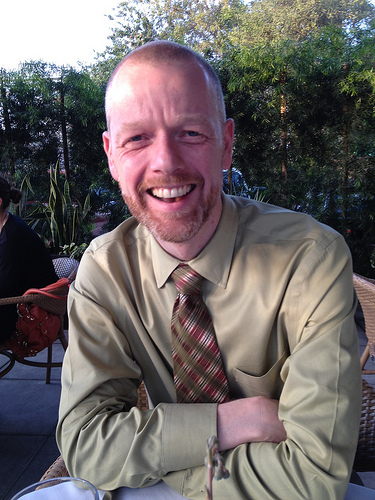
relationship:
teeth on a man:
[150, 183, 195, 198] [52, 40, 361, 498]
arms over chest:
[66, 365, 339, 497] [107, 237, 282, 404]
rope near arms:
[204, 435, 220, 498] [54, 257, 363, 497]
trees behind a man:
[238, 2, 371, 195] [52, 40, 361, 498]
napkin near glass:
[24, 476, 107, 499] [8, 474, 100, 498]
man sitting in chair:
[55, 40, 363, 500] [1, 249, 81, 374]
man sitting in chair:
[52, 40, 361, 498] [346, 267, 373, 370]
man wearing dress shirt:
[52, 40, 361, 498] [55, 189, 362, 499]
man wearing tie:
[52, 40, 361, 498] [169, 266, 229, 403]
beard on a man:
[122, 192, 219, 242] [52, 40, 361, 498]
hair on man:
[104, 40, 226, 132] [87, 50, 260, 313]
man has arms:
[55, 40, 363, 500] [49, 340, 372, 494]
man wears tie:
[55, 40, 363, 500] [165, 256, 220, 407]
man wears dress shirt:
[55, 40, 363, 500] [55, 189, 362, 499]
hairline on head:
[113, 38, 213, 82] [92, 34, 238, 150]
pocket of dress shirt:
[233, 356, 286, 395] [55, 189, 362, 499]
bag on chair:
[23, 275, 73, 301] [2, 253, 83, 388]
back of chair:
[20, 271, 88, 351] [2, 253, 83, 388]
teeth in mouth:
[152, 185, 191, 199] [143, 170, 201, 209]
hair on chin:
[132, 40, 218, 86] [137, 195, 226, 259]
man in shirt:
[55, 40, 363, 500] [74, 225, 356, 475]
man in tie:
[55, 40, 363, 500] [159, 252, 238, 400]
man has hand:
[52, 40, 361, 498] [224, 390, 293, 445]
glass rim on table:
[11, 476, 98, 498] [103, 480, 374, 498]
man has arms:
[52, 40, 361, 498] [62, 300, 362, 499]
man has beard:
[52, 40, 361, 498] [113, 172, 224, 242]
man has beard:
[52, 40, 361, 498] [123, 189, 225, 241]